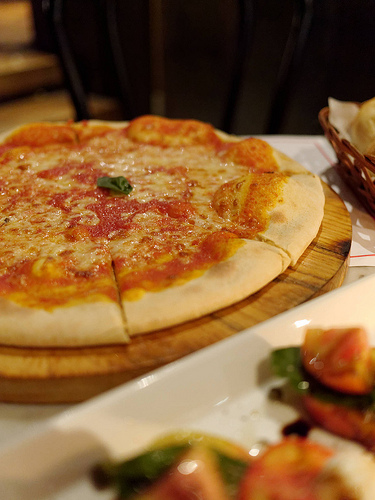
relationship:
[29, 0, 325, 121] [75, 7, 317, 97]
chair has rungs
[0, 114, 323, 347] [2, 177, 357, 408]
pizza on cutting board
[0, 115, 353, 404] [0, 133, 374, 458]
tray on table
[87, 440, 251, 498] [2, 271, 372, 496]
lettuce lying on tray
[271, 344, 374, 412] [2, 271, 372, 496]
lettuce lying on tray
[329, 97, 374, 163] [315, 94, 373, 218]
napkin lying in basket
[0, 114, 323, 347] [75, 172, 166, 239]
pizza has sauce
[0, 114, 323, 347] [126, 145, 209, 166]
pizza has cheese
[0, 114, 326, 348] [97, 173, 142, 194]
pizza has lettuce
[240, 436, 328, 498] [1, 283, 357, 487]
tomatoe on plate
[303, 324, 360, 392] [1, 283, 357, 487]
tomatoe on plate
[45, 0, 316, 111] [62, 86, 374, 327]
chair in back of table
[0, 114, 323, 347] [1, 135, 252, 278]
pizza has cheese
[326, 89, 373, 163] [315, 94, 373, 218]
food in basket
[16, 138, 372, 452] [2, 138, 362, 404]
food on table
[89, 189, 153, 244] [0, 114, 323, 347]
sauce on pizza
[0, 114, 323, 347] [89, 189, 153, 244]
pizza has sauce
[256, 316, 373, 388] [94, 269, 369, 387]
food on platter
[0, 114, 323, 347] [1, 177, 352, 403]
pizza on plate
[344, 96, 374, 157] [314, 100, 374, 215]
rolls in basket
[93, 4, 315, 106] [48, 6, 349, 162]
backrest on chair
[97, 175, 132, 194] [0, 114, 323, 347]
vegetable on pizza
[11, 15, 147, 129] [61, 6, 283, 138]
stairs behind chair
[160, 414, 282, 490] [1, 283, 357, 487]
sliced appetizers on plate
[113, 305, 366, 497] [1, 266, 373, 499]
appetizers on plate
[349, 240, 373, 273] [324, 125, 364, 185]
napkin under basket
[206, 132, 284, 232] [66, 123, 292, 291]
air pockets on pizza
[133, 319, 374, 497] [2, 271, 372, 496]
tomatoes resting tray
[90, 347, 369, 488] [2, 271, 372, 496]
basil resting tray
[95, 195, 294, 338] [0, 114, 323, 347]
slice of pizza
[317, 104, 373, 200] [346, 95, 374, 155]
basket of bread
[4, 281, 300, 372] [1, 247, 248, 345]
crust of pizza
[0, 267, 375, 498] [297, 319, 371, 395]
serving tray with tomato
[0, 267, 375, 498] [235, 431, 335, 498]
serving tray with tomato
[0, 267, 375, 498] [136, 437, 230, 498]
serving tray with tomato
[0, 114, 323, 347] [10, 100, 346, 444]
pizza on top board